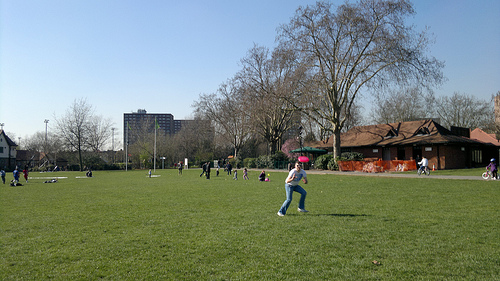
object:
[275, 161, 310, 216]
man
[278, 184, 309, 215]
jeans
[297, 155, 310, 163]
frisbee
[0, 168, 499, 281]
field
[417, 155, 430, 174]
person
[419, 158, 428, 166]
shirt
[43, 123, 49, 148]
light pole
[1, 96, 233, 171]
distance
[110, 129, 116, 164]
light pole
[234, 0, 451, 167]
tree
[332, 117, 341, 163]
trunk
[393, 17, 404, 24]
sparse leaves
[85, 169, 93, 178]
person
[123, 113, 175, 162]
building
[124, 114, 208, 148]
many windows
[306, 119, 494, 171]
building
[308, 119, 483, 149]
roof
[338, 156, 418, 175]
fence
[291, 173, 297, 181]
hand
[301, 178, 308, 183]
hand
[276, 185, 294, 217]
legs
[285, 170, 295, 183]
arm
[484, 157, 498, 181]
child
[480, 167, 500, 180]
bicycle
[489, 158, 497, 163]
bicycle helmet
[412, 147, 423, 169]
door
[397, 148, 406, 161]
door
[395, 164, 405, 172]
tag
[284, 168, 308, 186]
shirt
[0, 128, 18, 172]
building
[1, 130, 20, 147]
roof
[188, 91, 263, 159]
trees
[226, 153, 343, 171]
row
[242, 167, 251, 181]
child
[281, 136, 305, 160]
tree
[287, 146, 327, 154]
umbrella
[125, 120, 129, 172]
flagpole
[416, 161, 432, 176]
bicycles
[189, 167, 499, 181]
sidewalk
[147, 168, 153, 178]
child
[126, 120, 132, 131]
flag